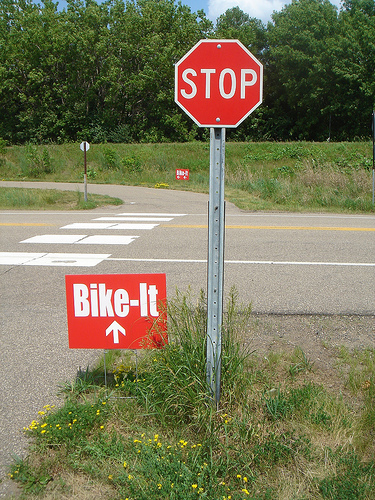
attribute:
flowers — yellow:
[18, 381, 267, 499]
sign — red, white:
[64, 273, 166, 350]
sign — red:
[61, 269, 170, 354]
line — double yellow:
[28, 216, 371, 240]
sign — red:
[62, 263, 174, 357]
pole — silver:
[207, 126, 225, 401]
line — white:
[19, 204, 185, 305]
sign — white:
[54, 267, 182, 365]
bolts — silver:
[206, 40, 223, 126]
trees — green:
[0, 0, 372, 143]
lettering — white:
[181, 68, 257, 99]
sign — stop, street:
[169, 33, 265, 132]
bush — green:
[136, 284, 260, 477]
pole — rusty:
[80, 139, 92, 202]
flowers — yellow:
[8, 356, 253, 497]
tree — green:
[257, 3, 373, 142]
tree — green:
[166, 9, 269, 141]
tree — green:
[80, 1, 212, 140]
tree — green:
[0, 0, 105, 138]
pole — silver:
[204, 134, 226, 399]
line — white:
[115, 210, 187, 218]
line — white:
[60, 221, 159, 231]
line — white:
[21, 232, 140, 246]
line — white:
[0, 252, 111, 268]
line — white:
[92, 215, 175, 223]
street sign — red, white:
[171, 36, 267, 128]